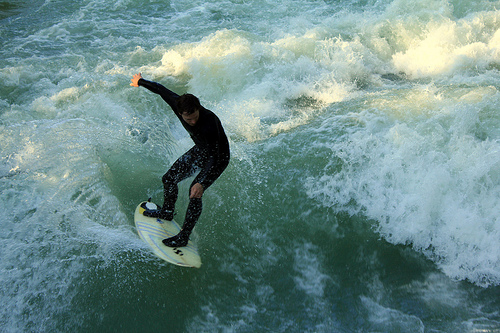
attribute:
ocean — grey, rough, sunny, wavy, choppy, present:
[2, 2, 499, 332]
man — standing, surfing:
[126, 72, 232, 250]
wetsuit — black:
[138, 79, 232, 248]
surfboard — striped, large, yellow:
[132, 197, 204, 270]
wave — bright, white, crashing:
[52, 5, 498, 135]